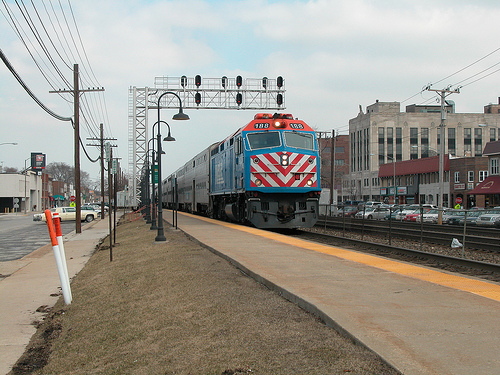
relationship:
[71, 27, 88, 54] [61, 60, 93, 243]
wire on pole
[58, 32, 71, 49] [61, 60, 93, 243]
wire on pole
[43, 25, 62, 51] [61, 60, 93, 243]
wire on pole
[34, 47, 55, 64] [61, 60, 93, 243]
wire on pole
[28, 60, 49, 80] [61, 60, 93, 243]
wire on pole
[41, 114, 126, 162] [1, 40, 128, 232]
lines on poles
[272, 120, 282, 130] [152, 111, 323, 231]
headlight on train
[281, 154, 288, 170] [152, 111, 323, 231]
headlight on train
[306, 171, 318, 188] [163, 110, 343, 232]
headlight on train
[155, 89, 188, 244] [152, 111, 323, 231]
street lamp next to train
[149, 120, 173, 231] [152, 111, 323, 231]
street lamp next to train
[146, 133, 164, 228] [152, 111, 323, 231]
street lamp next to train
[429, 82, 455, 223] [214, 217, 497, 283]
electric pole by tracks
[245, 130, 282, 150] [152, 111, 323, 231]
window on train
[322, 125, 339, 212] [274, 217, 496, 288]
pole next to tracks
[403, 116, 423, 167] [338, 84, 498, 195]
windows on building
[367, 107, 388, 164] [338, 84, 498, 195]
windows on building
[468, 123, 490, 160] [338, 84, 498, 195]
windows on building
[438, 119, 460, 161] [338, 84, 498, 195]
windows on building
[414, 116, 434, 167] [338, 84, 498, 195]
windows on building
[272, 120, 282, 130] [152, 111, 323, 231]
headlight of train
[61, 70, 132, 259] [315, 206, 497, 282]
pole next to tracks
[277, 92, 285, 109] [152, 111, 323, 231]
light warn train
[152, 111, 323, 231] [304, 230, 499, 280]
train on track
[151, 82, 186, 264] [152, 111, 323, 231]
lamp next to train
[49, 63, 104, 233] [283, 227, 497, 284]
electric pole next to tracks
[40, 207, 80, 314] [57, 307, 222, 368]
poles in ground